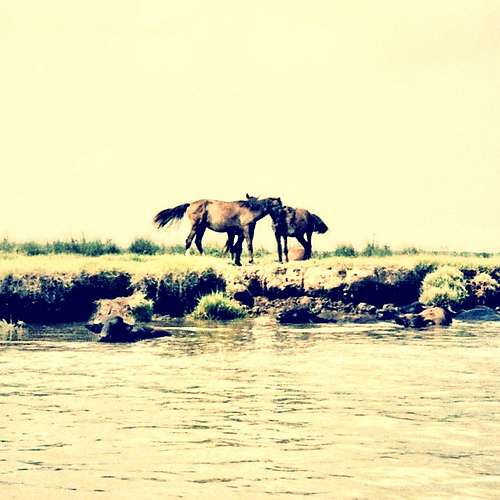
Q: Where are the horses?
A: Near a river.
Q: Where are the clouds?
A: In the sky.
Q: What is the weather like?
A: Cloudy.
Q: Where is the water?
A: In the river.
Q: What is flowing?
A: The water.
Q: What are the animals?
A: Horses.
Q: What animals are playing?
A: Horses.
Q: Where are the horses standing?
A: Beside the water.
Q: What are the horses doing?
A: Standing together.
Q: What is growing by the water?
A: Grass.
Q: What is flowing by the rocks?
A: River.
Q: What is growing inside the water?
A: Grass.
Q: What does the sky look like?
A: Cloudy.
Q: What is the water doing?
A: Moving.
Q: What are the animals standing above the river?
A: Horses.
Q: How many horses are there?
A: Two.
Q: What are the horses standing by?
A: A river.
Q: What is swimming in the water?
A: A buffalo.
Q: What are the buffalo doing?
A: Swimming.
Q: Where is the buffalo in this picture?
A: In the river.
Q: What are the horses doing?
A: Standing above the river.